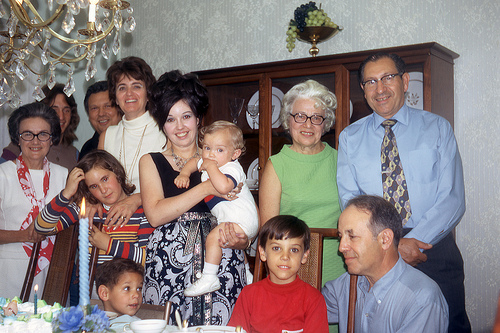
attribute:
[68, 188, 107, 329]
candle — tall, blue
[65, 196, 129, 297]
candle — lit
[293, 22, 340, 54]
bowl — gold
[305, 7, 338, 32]
grapes — plastic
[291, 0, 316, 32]
grapes — plastic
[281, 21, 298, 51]
grapes — plastic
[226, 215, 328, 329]
boy — small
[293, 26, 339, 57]
platter — gold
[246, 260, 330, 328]
shirt — striped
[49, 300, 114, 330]
flowers — blue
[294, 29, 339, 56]
bowl — raised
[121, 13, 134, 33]
crystal — hanging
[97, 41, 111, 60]
crystal — hanging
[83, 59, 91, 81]
crystal — hanging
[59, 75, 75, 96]
crystal — hanging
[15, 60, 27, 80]
crystal — hanging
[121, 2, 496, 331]
wallpaper — white, patterned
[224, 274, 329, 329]
shirt — red